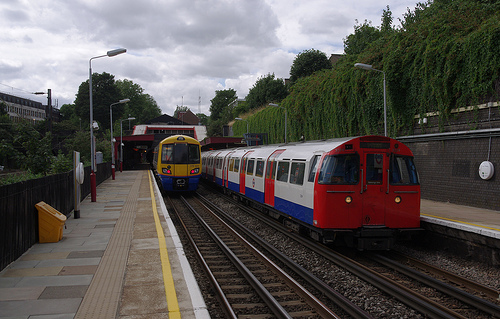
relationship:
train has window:
[197, 133, 422, 251] [273, 156, 289, 184]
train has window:
[197, 133, 422, 251] [288, 160, 305, 184]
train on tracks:
[197, 133, 422, 251] [151, 158, 499, 316]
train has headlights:
[197, 133, 422, 251] [339, 194, 353, 207]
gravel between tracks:
[193, 180, 413, 319] [151, 158, 499, 316]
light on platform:
[80, 46, 130, 206] [7, 162, 199, 318]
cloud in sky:
[18, 3, 301, 79] [2, 3, 428, 112]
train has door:
[197, 133, 422, 251] [260, 152, 288, 209]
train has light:
[197, 133, 422, 251] [391, 194, 404, 205]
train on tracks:
[154, 136, 204, 195] [151, 158, 499, 316]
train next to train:
[197, 133, 422, 251] [154, 136, 204, 195]